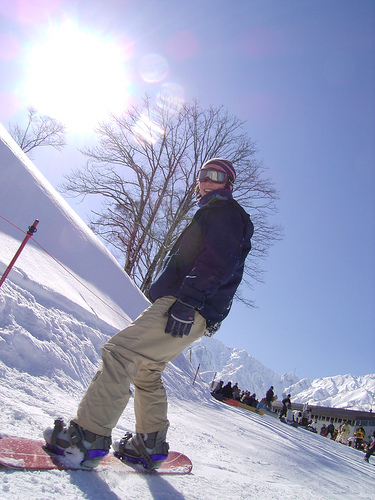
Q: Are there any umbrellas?
A: No, there are no umbrellas.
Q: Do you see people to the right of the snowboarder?
A: Yes, there are people to the right of the snowboarder.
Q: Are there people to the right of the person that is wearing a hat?
A: Yes, there are people to the right of the snowboarder.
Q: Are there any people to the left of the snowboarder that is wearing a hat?
A: No, the people are to the right of the snowboarder.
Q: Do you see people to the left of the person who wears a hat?
A: No, the people are to the right of the snowboarder.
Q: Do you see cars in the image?
A: No, there are no cars.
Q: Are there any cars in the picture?
A: No, there are no cars.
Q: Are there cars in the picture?
A: No, there are no cars.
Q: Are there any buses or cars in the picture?
A: No, there are no cars or buses.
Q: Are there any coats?
A: Yes, there is a coat.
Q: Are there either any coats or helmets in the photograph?
A: Yes, there is a coat.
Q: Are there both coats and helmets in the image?
A: No, there is a coat but no helmets.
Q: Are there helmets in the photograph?
A: No, there are no helmets.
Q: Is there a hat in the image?
A: Yes, there is a hat.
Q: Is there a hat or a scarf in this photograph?
A: Yes, there is a hat.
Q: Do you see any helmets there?
A: No, there are no helmets.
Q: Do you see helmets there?
A: No, there are no helmets.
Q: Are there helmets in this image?
A: No, there are no helmets.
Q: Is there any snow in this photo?
A: Yes, there is snow.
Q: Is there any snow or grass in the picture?
A: Yes, there is snow.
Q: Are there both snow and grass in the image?
A: No, there is snow but no grass.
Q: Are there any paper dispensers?
A: No, there are no paper dispensers.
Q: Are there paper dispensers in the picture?
A: No, there are no paper dispensers.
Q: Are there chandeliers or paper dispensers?
A: No, there are no paper dispensers or chandeliers.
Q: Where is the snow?
A: The snow is on the ground.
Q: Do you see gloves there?
A: Yes, there are gloves.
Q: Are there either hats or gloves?
A: Yes, there are gloves.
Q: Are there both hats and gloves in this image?
A: Yes, there are both gloves and a hat.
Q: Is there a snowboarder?
A: Yes, there is a snowboarder.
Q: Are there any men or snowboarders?
A: Yes, there is a snowboarder.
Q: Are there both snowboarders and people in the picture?
A: Yes, there are both a snowboarder and a person.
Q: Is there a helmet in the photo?
A: No, there are no helmets.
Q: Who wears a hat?
A: The snowboarder wears a hat.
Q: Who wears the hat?
A: The snowboarder wears a hat.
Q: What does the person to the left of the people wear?
A: The snowboarder wears a hat.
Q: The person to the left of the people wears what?
A: The snowboarder wears a hat.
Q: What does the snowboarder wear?
A: The snowboarder wears a hat.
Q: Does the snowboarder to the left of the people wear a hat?
A: Yes, the snowboarder wears a hat.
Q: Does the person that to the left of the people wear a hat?
A: Yes, the snowboarder wears a hat.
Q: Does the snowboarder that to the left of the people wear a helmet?
A: No, the snowboarder wears a hat.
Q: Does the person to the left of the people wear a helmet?
A: No, the snowboarder wears a hat.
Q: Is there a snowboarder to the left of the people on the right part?
A: Yes, there is a snowboarder to the left of the people.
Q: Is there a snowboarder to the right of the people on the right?
A: No, the snowboarder is to the left of the people.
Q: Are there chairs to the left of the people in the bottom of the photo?
A: No, there is a snowboarder to the left of the people.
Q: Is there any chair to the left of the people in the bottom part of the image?
A: No, there is a snowboarder to the left of the people.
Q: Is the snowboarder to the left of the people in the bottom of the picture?
A: Yes, the snowboarder is to the left of the people.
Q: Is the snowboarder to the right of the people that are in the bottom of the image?
A: No, the snowboarder is to the left of the people.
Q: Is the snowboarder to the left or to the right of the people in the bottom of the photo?
A: The snowboarder is to the left of the people.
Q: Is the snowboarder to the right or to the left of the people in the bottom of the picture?
A: The snowboarder is to the left of the people.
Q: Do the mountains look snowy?
A: Yes, the mountains are snowy.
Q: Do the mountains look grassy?
A: No, the mountains are snowy.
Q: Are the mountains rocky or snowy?
A: The mountains are snowy.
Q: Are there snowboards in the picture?
A: Yes, there is a snowboard.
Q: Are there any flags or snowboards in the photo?
A: Yes, there is a snowboard.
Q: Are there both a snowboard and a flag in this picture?
A: No, there is a snowboard but no flags.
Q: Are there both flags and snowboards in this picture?
A: No, there is a snowboard but no flags.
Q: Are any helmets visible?
A: No, there are no helmets.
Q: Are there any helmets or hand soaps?
A: No, there are no helmets or hand soaps.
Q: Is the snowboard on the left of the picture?
A: Yes, the snowboard is on the left of the image.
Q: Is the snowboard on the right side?
A: No, the snowboard is on the left of the image.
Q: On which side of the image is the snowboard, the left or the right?
A: The snowboard is on the left of the image.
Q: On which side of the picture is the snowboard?
A: The snowboard is on the left of the image.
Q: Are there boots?
A: Yes, there are boots.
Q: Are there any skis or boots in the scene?
A: Yes, there are boots.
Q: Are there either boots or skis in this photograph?
A: Yes, there are boots.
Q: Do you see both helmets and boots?
A: No, there are boots but no helmets.